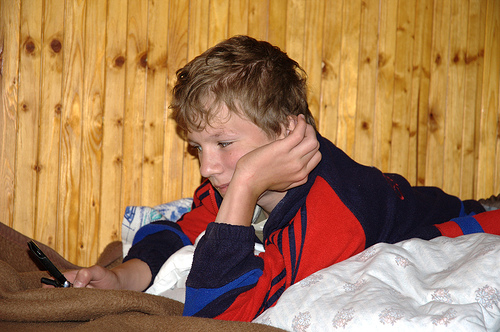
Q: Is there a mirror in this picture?
A: No, there are no mirrors.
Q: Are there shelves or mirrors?
A: No, there are no mirrors or shelves.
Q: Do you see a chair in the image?
A: No, there are no chairs.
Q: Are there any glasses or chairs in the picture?
A: No, there are no chairs or glasses.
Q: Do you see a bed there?
A: Yes, there is a bed.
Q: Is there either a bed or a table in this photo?
A: Yes, there is a bed.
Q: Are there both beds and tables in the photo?
A: No, there is a bed but no tables.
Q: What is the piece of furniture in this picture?
A: The piece of furniture is a bed.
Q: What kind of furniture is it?
A: The piece of furniture is a bed.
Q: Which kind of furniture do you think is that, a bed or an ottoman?
A: That is a bed.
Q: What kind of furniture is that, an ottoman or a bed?
A: That is a bed.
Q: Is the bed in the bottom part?
A: Yes, the bed is in the bottom of the image.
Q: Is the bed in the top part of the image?
A: No, the bed is in the bottom of the image.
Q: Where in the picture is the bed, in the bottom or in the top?
A: The bed is in the bottom of the image.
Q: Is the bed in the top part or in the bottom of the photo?
A: The bed is in the bottom of the image.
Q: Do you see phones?
A: Yes, there is a phone.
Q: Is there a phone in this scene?
A: Yes, there is a phone.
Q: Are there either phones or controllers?
A: Yes, there is a phone.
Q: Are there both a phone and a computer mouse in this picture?
A: No, there is a phone but no computer mice.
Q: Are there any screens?
A: No, there are no screens.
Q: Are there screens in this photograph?
A: No, there are no screens.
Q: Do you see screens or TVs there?
A: No, there are no screens or tvs.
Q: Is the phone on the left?
A: Yes, the phone is on the left of the image.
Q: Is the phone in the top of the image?
A: No, the phone is in the bottom of the image.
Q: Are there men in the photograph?
A: No, there are no men.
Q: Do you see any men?
A: No, there are no men.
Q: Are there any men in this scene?
A: No, there are no men.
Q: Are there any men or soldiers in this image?
A: No, there are no men or soldiers.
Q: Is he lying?
A: Yes, the boy is lying.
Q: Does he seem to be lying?
A: Yes, the boy is lying.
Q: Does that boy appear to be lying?
A: Yes, the boy is lying.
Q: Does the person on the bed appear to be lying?
A: Yes, the boy is lying.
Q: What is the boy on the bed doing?
A: The boy is lying.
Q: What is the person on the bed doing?
A: The boy is lying.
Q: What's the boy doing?
A: The boy is lying.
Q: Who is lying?
A: The boy is lying.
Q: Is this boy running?
A: No, the boy is lying.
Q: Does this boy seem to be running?
A: No, the boy is lying.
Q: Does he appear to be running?
A: No, the boy is lying.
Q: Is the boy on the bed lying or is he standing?
A: The boy is lying.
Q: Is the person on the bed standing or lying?
A: The boy is lying.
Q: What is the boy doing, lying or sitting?
A: The boy is lying.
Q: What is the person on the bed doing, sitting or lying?
A: The boy is lying.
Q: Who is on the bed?
A: The boy is on the bed.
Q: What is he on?
A: The boy is on the bed.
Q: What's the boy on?
A: The boy is on the bed.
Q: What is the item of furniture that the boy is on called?
A: The piece of furniture is a bed.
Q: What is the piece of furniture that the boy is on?
A: The piece of furniture is a bed.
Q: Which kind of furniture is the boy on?
A: The boy is on the bed.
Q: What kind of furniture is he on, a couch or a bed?
A: The boy is on a bed.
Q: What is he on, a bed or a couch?
A: The boy is on a bed.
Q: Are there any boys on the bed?
A: Yes, there is a boy on the bed.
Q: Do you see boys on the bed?
A: Yes, there is a boy on the bed.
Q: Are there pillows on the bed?
A: No, there is a boy on the bed.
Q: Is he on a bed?
A: Yes, the boy is on a bed.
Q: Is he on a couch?
A: No, the boy is on a bed.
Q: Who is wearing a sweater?
A: The boy is wearing a sweater.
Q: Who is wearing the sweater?
A: The boy is wearing a sweater.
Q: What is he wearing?
A: The boy is wearing a sweater.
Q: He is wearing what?
A: The boy is wearing a sweater.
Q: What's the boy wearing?
A: The boy is wearing a sweater.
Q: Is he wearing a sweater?
A: Yes, the boy is wearing a sweater.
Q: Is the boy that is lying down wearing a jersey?
A: No, the boy is wearing a sweater.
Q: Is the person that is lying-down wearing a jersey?
A: No, the boy is wearing a sweater.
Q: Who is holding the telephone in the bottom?
A: The boy is holding the phone.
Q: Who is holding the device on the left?
A: The boy is holding the phone.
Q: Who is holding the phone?
A: The boy is holding the phone.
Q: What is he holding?
A: The boy is holding the phone.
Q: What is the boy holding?
A: The boy is holding the phone.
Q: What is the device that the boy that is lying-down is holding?
A: The device is a phone.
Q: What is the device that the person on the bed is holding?
A: The device is a phone.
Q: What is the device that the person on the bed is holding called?
A: The device is a phone.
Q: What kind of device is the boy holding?
A: The boy is holding the telephone.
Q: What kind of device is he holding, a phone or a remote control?
A: The boy is holding a phone.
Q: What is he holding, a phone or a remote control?
A: The boy is holding a phone.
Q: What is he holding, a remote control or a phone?
A: The boy is holding a phone.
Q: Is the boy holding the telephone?
A: Yes, the boy is holding the telephone.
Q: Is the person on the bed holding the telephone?
A: Yes, the boy is holding the telephone.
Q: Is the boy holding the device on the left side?
A: Yes, the boy is holding the telephone.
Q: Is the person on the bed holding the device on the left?
A: Yes, the boy is holding the telephone.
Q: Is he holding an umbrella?
A: No, the boy is holding the telephone.